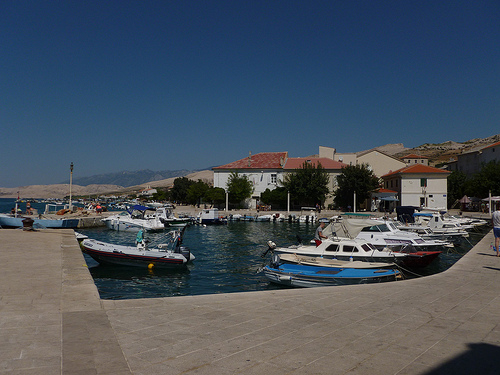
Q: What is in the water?
A: Boats.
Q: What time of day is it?
A: Afternoon.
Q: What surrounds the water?
A: Deck.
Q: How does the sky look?
A: Blue and clear.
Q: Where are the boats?
A: In the water.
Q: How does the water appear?
A: Calm.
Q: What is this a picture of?
A: A marina.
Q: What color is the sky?
A: Blue.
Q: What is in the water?
A: Boats.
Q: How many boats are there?
A: Nine.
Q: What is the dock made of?
A: Cement.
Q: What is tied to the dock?
A: Boats.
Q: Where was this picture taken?
A: At a boatyard.